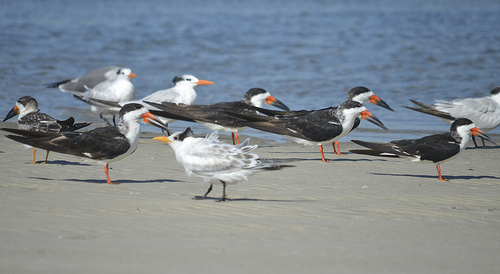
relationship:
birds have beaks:
[143, 86, 380, 162] [270, 94, 290, 113]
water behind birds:
[7, 1, 499, 111] [143, 86, 380, 162]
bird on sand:
[155, 129, 289, 203] [9, 181, 498, 267]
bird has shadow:
[155, 129, 289, 203] [209, 192, 312, 205]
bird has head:
[155, 129, 289, 203] [169, 128, 203, 147]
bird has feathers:
[155, 129, 289, 203] [186, 138, 260, 184]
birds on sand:
[143, 86, 380, 162] [9, 181, 498, 267]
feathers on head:
[186, 138, 260, 184] [169, 128, 203, 147]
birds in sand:
[143, 86, 380, 162] [9, 181, 498, 267]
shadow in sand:
[209, 192, 312, 205] [9, 181, 498, 267]